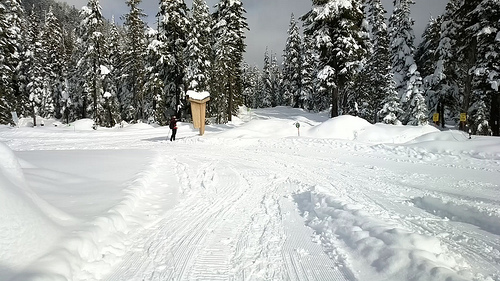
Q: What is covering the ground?
A: Snow.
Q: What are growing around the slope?
A: Trees.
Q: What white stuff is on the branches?
A: Snow.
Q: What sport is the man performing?
A: Skiing.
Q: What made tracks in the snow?
A: Skis and snowboards.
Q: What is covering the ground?
A: Snow.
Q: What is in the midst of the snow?
A: Tire tracks.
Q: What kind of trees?
A: Evergreen.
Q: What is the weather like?
A: Cloudy.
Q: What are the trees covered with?
A: Snow.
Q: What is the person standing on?
A: Snow.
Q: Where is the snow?
A: On the ground.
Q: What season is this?
A: Winter.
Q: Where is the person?
A: In front of the trees.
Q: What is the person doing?
A: Reading a sign.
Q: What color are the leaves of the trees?
A: Green.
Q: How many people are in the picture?
A: One.